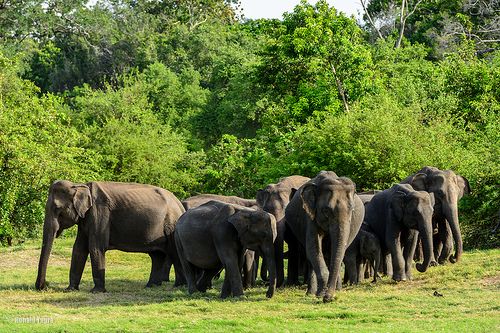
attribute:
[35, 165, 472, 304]
elephants — in a herd, gray, grouped, large, walking, standing, side by side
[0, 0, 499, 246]
greenery — green, growing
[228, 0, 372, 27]
sky — blue, clear, bright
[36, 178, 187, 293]
elephant — turned to side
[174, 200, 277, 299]
elephant — in the middle, small, in front, grey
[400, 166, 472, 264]
elephant — farthest to right, on right side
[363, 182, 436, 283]
elephant — on right side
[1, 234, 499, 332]
grass — green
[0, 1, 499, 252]
leaves — green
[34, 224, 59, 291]
trunk — long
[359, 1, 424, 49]
branches — bare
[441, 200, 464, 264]
trunk — curled, curved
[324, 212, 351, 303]
trunk — slanted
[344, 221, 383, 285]
baby elephant — hidden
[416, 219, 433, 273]
trunk — curved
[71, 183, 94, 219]
ear — grey